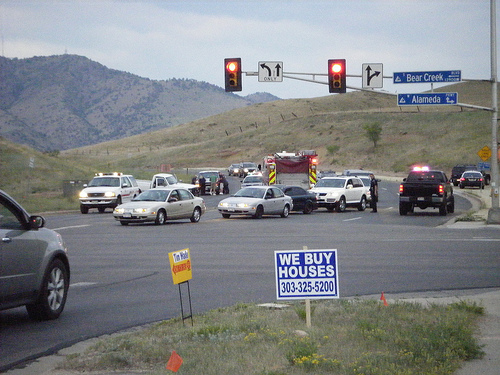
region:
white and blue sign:
[253, 246, 408, 312]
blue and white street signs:
[396, 70, 467, 110]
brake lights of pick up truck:
[398, 180, 459, 222]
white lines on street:
[75, 273, 90, 300]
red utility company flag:
[156, 352, 212, 372]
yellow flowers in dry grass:
[293, 338, 306, 366]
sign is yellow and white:
[161, 243, 205, 295]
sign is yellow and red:
[161, 252, 186, 272]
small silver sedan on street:
[126, 192, 192, 234]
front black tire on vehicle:
[29, 243, 94, 327]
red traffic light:
[225, 59, 240, 93]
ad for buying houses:
[273, 247, 338, 334]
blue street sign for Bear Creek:
[394, 68, 466, 88]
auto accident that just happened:
[131, 168, 226, 197]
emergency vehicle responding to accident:
[267, 149, 317, 186]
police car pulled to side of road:
[456, 167, 487, 193]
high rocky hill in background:
[2, 52, 282, 145]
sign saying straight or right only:
[359, 59, 384, 94]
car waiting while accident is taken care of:
[4, 179, 70, 326]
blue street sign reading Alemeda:
[401, 94, 461, 109]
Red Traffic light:
[220, 53, 246, 98]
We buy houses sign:
[271, 243, 346, 310]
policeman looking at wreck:
[364, 168, 383, 218]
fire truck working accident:
[260, 148, 324, 201]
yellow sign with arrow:
[163, 246, 199, 285]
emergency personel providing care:
[186, 171, 232, 197]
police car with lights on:
[75, 168, 137, 218]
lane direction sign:
[255, 54, 290, 90]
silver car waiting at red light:
[111, 183, 211, 230]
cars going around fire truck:
[211, 172, 368, 222]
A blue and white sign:
[262, 239, 358, 308]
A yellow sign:
[159, 242, 202, 332]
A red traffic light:
[214, 47, 251, 104]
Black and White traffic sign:
[250, 52, 292, 99]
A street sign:
[388, 63, 470, 90]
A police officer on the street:
[359, 165, 386, 216]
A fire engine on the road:
[252, 144, 325, 211]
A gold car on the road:
[107, 176, 214, 232]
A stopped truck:
[391, 167, 463, 227]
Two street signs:
[387, 62, 474, 120]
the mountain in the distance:
[5, 53, 257, 138]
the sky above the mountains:
[3, 0, 499, 100]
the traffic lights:
[220, 58, 347, 95]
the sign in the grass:
[276, 248, 336, 334]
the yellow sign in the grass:
[168, 245, 199, 331]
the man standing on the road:
[367, 172, 379, 210]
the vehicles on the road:
[0, 140, 496, 330]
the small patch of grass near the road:
[97, 308, 498, 365]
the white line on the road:
[341, 213, 361, 228]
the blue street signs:
[392, 66, 466, 108]